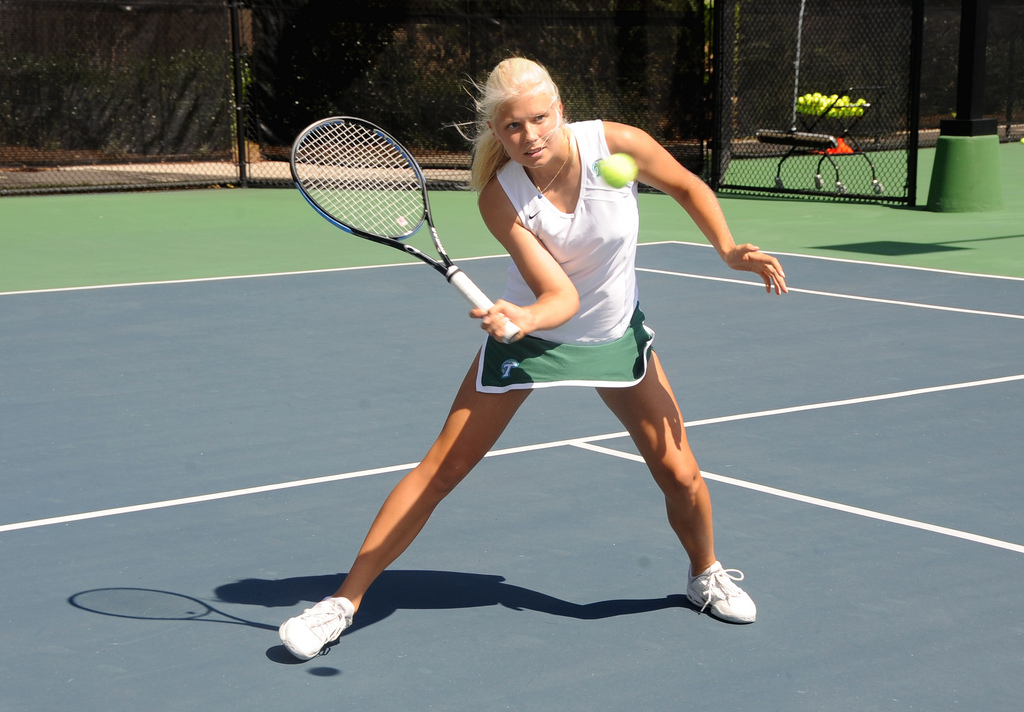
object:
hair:
[441, 58, 569, 191]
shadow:
[68, 585, 282, 632]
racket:
[287, 115, 522, 345]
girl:
[277, 53, 778, 663]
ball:
[599, 153, 638, 189]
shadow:
[309, 666, 341, 676]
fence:
[5, 0, 237, 194]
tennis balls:
[796, 92, 872, 120]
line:
[630, 266, 1022, 319]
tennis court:
[2, 190, 1024, 712]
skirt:
[476, 301, 656, 393]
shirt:
[492, 120, 642, 340]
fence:
[233, 0, 717, 194]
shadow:
[68, 570, 712, 677]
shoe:
[277, 596, 356, 660]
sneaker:
[685, 561, 756, 625]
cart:
[715, 81, 913, 206]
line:
[569, 440, 1024, 553]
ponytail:
[468, 129, 512, 196]